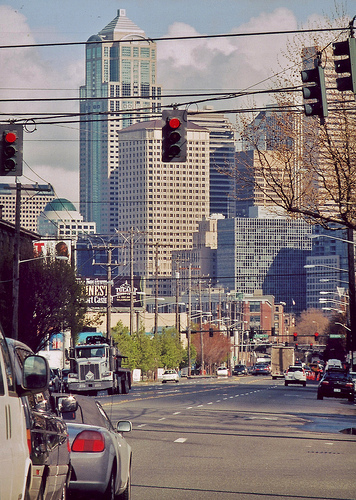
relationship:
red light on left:
[4, 131, 18, 143] [3, 15, 25, 308]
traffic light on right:
[286, 322, 324, 357] [166, 12, 199, 294]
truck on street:
[68, 335, 132, 397] [54, 364, 354, 498]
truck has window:
[68, 335, 132, 397] [73, 343, 111, 358]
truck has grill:
[68, 335, 132, 397] [80, 362, 100, 376]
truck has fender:
[68, 335, 132, 397] [69, 378, 114, 390]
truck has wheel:
[66, 343, 132, 396] [108, 372, 130, 392]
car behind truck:
[154, 364, 181, 386] [68, 335, 132, 397]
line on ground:
[132, 382, 220, 394] [99, 394, 353, 495]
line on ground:
[154, 390, 262, 407] [99, 394, 353, 495]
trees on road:
[125, 333, 188, 372] [116, 378, 200, 412]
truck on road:
[68, 335, 132, 397] [1, 374, 352, 497]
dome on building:
[41, 198, 75, 209] [37, 199, 96, 238]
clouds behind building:
[0, 5, 354, 193] [78, 8, 161, 232]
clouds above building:
[0, 5, 354, 193] [78, 8, 161, 232]